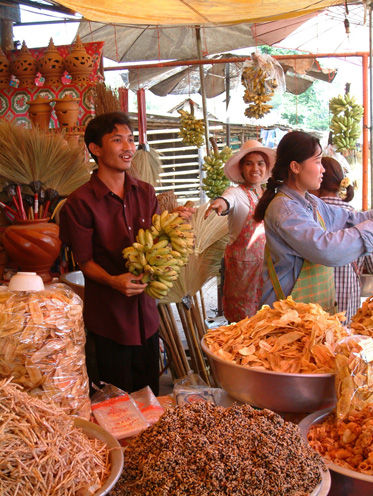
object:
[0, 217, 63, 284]
pot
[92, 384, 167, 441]
bag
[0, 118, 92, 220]
broom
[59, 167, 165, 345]
shirt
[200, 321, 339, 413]
bowl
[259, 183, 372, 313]
shirt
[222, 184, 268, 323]
apron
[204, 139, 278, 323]
woman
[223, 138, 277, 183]
hat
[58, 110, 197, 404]
guy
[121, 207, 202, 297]
bananas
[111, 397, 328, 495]
food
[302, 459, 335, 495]
platter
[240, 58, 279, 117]
bananas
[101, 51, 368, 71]
pole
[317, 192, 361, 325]
shirt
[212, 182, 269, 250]
shirt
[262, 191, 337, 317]
apron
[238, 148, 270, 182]
head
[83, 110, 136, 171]
head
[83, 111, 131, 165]
hair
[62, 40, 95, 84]
pot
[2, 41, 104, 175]
shelf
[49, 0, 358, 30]
canopy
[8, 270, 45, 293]
bowl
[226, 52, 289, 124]
bag